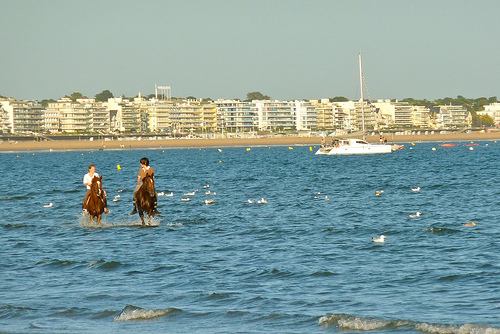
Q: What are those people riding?
A: Horses.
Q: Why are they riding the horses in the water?
A: It's fun.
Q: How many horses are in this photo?
A: Two.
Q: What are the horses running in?
A: The water.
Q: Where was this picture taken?
A: Malta.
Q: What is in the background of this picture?
A: Buildings.